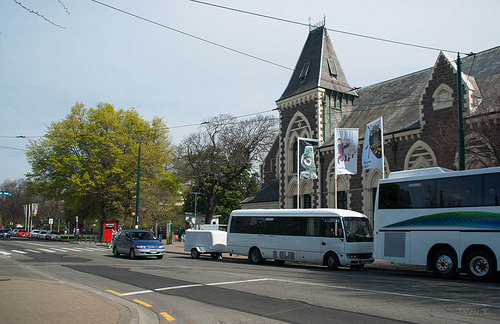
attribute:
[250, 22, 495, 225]
building — brick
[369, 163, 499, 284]
bus — white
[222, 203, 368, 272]
bus — white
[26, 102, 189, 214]
leaves — yellow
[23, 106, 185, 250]
tree — large, round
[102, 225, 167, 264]
car — blue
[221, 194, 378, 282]
van — white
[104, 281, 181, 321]
dashes — yellow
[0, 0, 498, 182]
sky — blue, clear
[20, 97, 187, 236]
tree — green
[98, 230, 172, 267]
car — blue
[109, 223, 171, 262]
car — blue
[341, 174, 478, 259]
bus — parked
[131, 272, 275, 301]
white line — dashed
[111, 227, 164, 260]
car — blue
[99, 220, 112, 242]
booth — red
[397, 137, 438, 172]
arch — white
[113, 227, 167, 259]
car — blue, small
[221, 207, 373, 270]
bus — smaller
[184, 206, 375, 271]
van — white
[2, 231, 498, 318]
road — busy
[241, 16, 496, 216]
building — church like